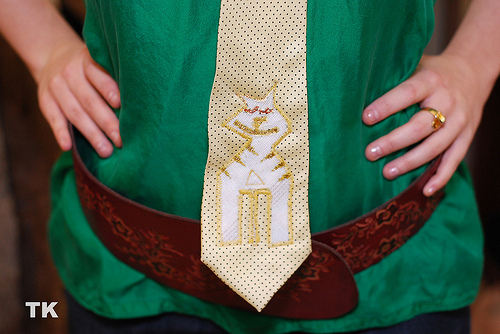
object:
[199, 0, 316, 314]
cat tie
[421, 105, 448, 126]
ring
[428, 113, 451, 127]
jewel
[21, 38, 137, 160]
hands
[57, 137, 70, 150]
fingernail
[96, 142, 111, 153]
fingernail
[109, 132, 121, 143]
fingernail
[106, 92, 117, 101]
fingernail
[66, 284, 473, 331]
jeans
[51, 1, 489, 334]
top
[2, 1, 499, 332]
person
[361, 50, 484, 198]
hand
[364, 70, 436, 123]
finger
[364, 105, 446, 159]
finger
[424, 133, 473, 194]
finger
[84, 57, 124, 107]
finger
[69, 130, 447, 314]
belt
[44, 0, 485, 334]
shirt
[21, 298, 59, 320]
tk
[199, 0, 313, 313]
polka dots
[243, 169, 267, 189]
triangle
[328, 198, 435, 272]
design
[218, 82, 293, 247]
cat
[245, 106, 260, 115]
eye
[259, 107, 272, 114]
eye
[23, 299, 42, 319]
letter t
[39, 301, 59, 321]
letter k